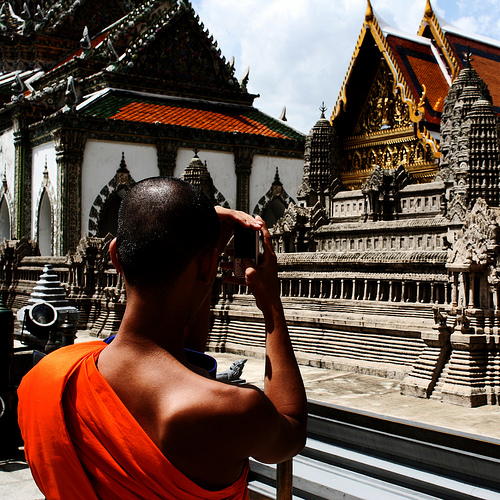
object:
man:
[16, 178, 308, 497]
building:
[37, 125, 310, 263]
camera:
[234, 221, 259, 275]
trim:
[370, 26, 466, 138]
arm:
[240, 289, 308, 464]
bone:
[162, 375, 181, 454]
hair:
[115, 176, 218, 289]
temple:
[209, 0, 499, 498]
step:
[258, 302, 473, 414]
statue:
[425, 119, 495, 385]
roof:
[329, 0, 500, 151]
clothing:
[16, 341, 250, 497]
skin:
[152, 309, 247, 429]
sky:
[232, 9, 352, 122]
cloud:
[236, 16, 315, 165]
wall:
[170, 141, 280, 200]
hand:
[244, 225, 280, 303]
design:
[360, 82, 415, 156]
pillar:
[465, 99, 499, 221]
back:
[15, 338, 245, 497]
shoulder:
[18, 335, 105, 431]